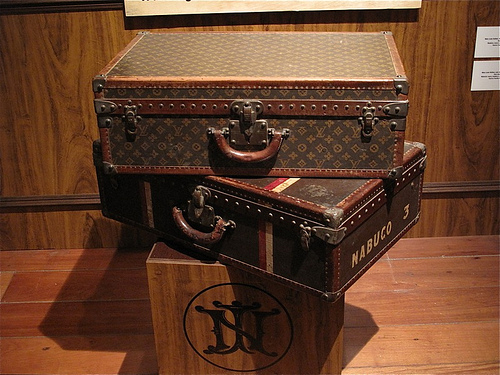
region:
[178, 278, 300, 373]
Black logo with a circular rim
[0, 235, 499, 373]
Floor made of brown wood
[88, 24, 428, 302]
Box on top of another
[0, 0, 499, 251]
Wall made of brown wood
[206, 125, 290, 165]
Handle of a box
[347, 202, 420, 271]
Writings on the side of a box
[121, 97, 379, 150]
Shut latches of a box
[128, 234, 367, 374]
Tall square box on the floor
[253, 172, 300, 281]
White and red colored bands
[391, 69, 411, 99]
Metal frames at a corner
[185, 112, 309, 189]
a handle on a suit case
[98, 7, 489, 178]
a little brown suit case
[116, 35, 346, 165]
a design on a suit case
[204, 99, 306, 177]
a brown handle on a suit case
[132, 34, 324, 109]
the top of a suit case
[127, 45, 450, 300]
suit cases stacks on top of each other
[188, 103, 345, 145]
a lock on a suit case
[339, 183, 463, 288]
letters on a suit case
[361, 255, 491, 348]
a brown floor in a room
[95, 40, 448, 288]
a suit case in a room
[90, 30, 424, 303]
Two suitcases are together.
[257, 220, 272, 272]
Stripes are on the suitcase.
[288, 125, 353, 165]
The suitcase is patterned.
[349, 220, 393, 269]
The word Nabuco is on the suitcase.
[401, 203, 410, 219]
The number three is on the suitcase.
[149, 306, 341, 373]
A box is under the suitcases.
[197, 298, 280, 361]
A symbol is on the box.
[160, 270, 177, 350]
The box is made of wood.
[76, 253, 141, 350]
The suitcase's shadow is on the floor.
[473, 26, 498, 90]
Two signs are on the wall.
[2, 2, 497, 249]
wood surface of wall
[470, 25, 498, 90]
two white cards on wall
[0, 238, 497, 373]
surface of wood floor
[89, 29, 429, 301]
two stacked antique suitcases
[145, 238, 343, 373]
wood box with emblem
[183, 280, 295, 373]
two letters in circle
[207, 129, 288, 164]
leather handle on suitcase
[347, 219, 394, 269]
word on side of suitcase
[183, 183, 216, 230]
metal latch on suitcase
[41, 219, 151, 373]
shadow on wall and floor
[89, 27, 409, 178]
old luggage with brown trim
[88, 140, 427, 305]
brown luggage with red and white stripe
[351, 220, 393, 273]
nabuco written on luggage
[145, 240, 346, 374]
wooden block with black engraving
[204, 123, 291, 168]
leather handle on luggage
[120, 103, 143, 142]
metal latch on luggage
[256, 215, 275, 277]
red and white stripes on luggage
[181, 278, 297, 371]
engraving on wood block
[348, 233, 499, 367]
wood plank flooring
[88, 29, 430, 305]
two pieces of luggage on block